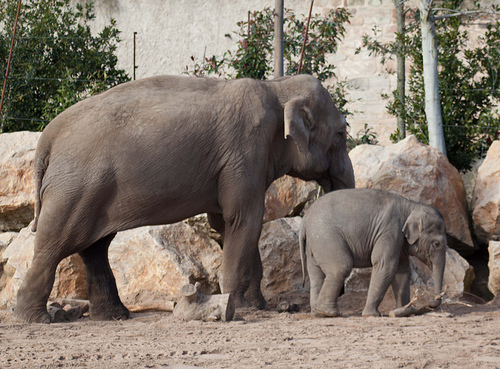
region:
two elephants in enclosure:
[16, 52, 469, 330]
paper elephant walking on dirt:
[289, 182, 466, 328]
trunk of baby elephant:
[427, 261, 454, 308]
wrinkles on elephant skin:
[204, 118, 252, 174]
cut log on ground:
[167, 276, 245, 331]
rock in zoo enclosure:
[379, 137, 469, 188]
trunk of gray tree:
[417, 59, 452, 143]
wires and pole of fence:
[47, 19, 149, 89]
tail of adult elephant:
[22, 136, 57, 238]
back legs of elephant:
[9, 225, 138, 344]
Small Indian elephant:
[307, 180, 465, 325]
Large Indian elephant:
[53, 54, 338, 301]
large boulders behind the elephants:
[1, 144, 481, 321]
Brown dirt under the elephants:
[0, 306, 457, 367]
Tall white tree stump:
[415, 8, 447, 148]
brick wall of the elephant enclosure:
[112, 10, 485, 132]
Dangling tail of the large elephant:
[31, 148, 50, 224]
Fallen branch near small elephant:
[378, 280, 466, 332]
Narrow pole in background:
[131, 29, 156, 80]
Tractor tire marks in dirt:
[62, 343, 223, 355]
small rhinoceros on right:
[295, 183, 454, 323]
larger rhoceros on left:
[10, 66, 365, 328]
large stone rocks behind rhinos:
[0, 126, 497, 306]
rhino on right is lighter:
[22, 67, 452, 331]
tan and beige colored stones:
[0, 118, 498, 308]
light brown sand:
[2, 303, 498, 367]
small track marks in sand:
[2, 311, 498, 367]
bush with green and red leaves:
[175, 12, 346, 157]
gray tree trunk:
[400, 0, 469, 223]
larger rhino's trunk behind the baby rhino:
[311, 161, 360, 286]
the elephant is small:
[305, 192, 437, 318]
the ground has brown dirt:
[193, 336, 379, 366]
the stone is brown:
[387, 147, 465, 189]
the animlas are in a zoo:
[38, 72, 455, 332]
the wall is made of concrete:
[150, 21, 230, 46]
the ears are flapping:
[270, 107, 316, 160]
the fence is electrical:
[25, 16, 56, 137]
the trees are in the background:
[363, 26, 484, 141]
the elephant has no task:
[300, 131, 345, 194]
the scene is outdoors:
[5, 30, 498, 362]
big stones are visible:
[390, 130, 487, 225]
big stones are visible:
[4, 108, 89, 272]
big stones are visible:
[84, 195, 238, 366]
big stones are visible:
[30, 114, 68, 265]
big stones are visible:
[448, 141, 493, 219]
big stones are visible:
[427, 167, 498, 315]